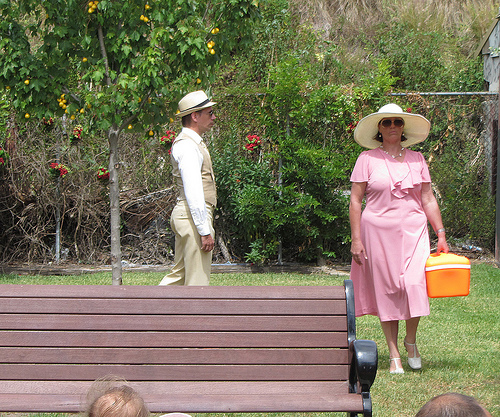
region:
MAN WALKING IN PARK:
[169, 64, 223, 296]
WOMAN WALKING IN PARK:
[334, 85, 428, 362]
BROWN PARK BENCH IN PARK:
[17, 296, 377, 413]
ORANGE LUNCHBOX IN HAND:
[429, 235, 477, 318]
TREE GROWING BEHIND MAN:
[18, 6, 243, 152]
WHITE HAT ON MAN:
[177, 81, 217, 116]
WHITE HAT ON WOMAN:
[357, 95, 441, 143]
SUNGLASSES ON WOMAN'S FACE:
[380, 114, 405, 129]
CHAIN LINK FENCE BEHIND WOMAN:
[318, 88, 498, 233]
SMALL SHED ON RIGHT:
[463, 19, 498, 128]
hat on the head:
[181, 95, 218, 114]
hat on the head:
[383, 98, 440, 118]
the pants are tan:
[183, 265, 219, 279]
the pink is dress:
[370, 206, 415, 236]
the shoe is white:
[410, 359, 425, 375]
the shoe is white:
[384, 366, 409, 375]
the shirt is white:
[187, 146, 206, 179]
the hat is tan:
[390, 101, 407, 115]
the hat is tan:
[173, 90, 197, 100]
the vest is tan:
[205, 168, 216, 188]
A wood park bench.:
[0, 279, 372, 409]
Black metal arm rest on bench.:
[343, 280, 382, 415]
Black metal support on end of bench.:
[342, 277, 382, 414]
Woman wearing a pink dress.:
[345, 98, 444, 378]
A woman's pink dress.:
[348, 147, 431, 323]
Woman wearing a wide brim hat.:
[351, 95, 434, 157]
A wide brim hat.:
[351, 99, 431, 151]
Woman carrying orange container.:
[347, 100, 472, 345]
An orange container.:
[420, 245, 472, 297]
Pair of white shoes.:
[384, 340, 425, 378]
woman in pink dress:
[338, 140, 450, 321]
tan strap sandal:
[381, 333, 428, 378]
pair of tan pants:
[157, 201, 221, 288]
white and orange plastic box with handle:
[423, 246, 478, 305]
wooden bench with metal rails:
[3, 273, 381, 415]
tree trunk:
[98, 141, 142, 294]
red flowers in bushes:
[46, 113, 174, 191]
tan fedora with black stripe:
[170, 84, 220, 123]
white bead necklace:
[376, 138, 408, 164]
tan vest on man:
[164, 127, 228, 213]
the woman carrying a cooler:
[348, 102, 469, 374]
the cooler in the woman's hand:
[424, 248, 471, 296]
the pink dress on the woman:
[349, 145, 431, 322]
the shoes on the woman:
[389, 335, 421, 372]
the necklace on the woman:
[378, 143, 404, 158]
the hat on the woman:
[354, 103, 429, 150]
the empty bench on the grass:
[0, 283, 377, 415]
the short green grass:
[0, 263, 498, 415]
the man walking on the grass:
[157, 89, 217, 286]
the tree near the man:
[0, 0, 261, 285]